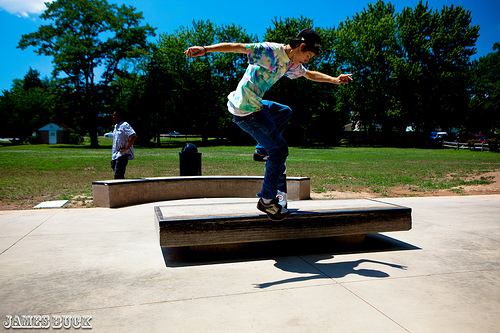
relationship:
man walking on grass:
[106, 115, 133, 178] [5, 150, 477, 197]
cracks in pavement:
[20, 202, 95, 286] [5, 178, 483, 322]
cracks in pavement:
[0, 205, 66, 280] [1, 207, 498, 327]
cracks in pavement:
[299, 260, 412, 332] [5, 178, 483, 322]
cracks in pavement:
[175, 284, 290, 310] [5, 178, 483, 322]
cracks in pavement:
[299, 261, 367, 304] [5, 239, 499, 319]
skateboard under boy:
[264, 156, 288, 218] [182, 28, 351, 223]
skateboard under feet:
[264, 156, 288, 218] [252, 147, 290, 220]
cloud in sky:
[3, 2, 50, 16] [146, 0, 333, 22]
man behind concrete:
[106, 109, 137, 180] [94, 166, 309, 211]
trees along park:
[0, 2, 497, 152] [4, 0, 496, 211]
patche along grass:
[386, 181, 418, 196] [4, 141, 484, 209]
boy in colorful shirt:
[182, 28, 351, 223] [225, 41, 307, 117]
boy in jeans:
[182, 28, 351, 223] [231, 99, 292, 196]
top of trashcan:
[175, 141, 199, 153] [173, 136, 207, 176]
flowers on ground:
[72, 193, 84, 203] [43, 178, 90, 231]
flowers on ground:
[350, 126, 437, 138] [9, 140, 485, 317]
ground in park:
[0, 134, 499, 333] [2, 2, 494, 329]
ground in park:
[0, 134, 499, 333] [3, 142, 498, 332]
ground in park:
[15, 265, 155, 302] [19, 19, 489, 314]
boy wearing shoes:
[181, 12, 373, 253] [257, 197, 290, 217]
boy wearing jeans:
[182, 28, 351, 223] [229, 99, 290, 200]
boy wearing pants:
[182, 28, 351, 223] [222, 92, 310, 200]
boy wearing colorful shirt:
[182, 28, 351, 223] [225, 41, 307, 117]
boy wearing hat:
[182, 28, 351, 223] [284, 24, 327, 49]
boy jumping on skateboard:
[182, 28, 351, 223] [264, 150, 291, 216]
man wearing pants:
[106, 109, 137, 180] [113, 152, 128, 177]